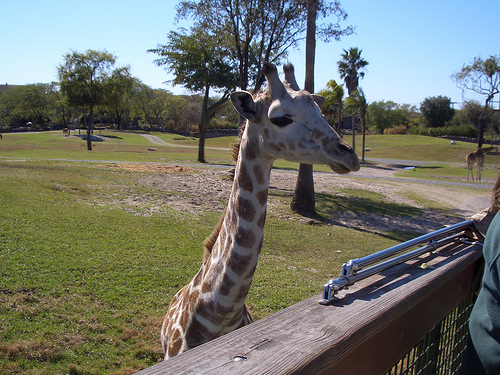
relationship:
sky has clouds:
[3, 1, 487, 123] [365, 81, 416, 108]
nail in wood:
[224, 352, 254, 367] [112, 197, 495, 374]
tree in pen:
[54, 44, 126, 150] [3, 124, 499, 374]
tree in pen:
[148, 0, 357, 162] [3, 124, 499, 374]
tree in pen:
[180, 0, 342, 171] [3, 124, 499, 374]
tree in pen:
[284, 0, 332, 219] [3, 124, 499, 374]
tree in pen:
[449, 53, 499, 150] [3, 124, 499, 374]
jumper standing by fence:
[467, 183, 500, 375] [340, 207, 463, 362]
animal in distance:
[160, 61, 361, 363] [29, 31, 234, 191]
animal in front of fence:
[160, 61, 361, 363] [251, 311, 391, 373]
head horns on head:
[263, 62, 300, 93] [208, 45, 414, 193]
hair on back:
[215, 132, 245, 204] [160, 201, 251, 303]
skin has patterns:
[148, 82, 333, 353] [173, 286, 234, 316]